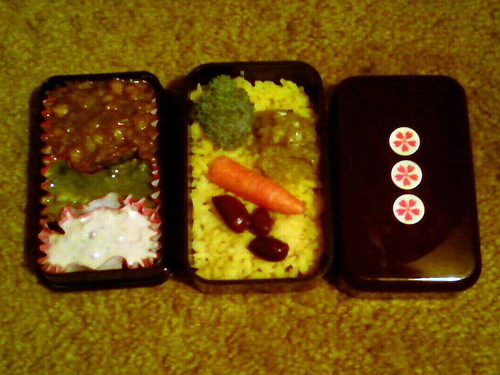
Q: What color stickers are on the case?
A: Pink, white.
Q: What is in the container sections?
A: Food.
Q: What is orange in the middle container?
A: Carrot.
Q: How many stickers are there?
A: 3.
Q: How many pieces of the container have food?
A: 2.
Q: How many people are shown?
A: 0.